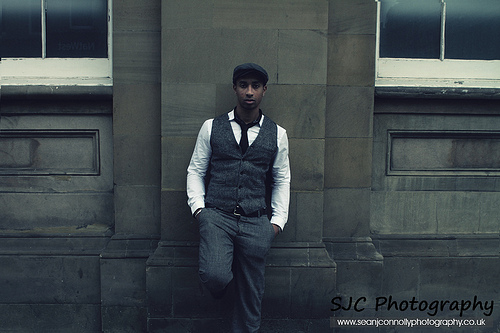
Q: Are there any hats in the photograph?
A: Yes, there is a hat.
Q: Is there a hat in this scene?
A: Yes, there is a hat.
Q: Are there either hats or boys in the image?
A: Yes, there is a hat.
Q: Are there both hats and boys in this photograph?
A: No, there is a hat but no boys.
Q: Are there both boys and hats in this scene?
A: No, there is a hat but no boys.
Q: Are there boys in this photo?
A: No, there are no boys.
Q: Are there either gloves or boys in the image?
A: No, there are no boys or gloves.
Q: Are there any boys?
A: No, there are no boys.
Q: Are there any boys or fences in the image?
A: No, there are no boys or fences.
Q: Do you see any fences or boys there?
A: No, there are no boys or fences.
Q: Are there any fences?
A: No, there are no fences.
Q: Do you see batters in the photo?
A: No, there are no batters.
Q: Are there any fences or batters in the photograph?
A: No, there are no batters or fences.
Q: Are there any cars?
A: No, there are no cars.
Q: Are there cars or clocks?
A: No, there are no cars or clocks.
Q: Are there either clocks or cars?
A: No, there are no cars or clocks.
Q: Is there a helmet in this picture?
A: No, there are no helmets.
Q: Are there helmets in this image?
A: No, there are no helmets.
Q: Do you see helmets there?
A: No, there are no helmets.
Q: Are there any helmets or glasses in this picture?
A: No, there are no helmets or glasses.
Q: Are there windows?
A: Yes, there is a window.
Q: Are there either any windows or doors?
A: Yes, there is a window.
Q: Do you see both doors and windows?
A: No, there is a window but no doors.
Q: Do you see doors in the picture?
A: No, there are no doors.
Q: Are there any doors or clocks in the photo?
A: No, there are no doors or clocks.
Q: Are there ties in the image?
A: Yes, there is a tie.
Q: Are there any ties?
A: Yes, there is a tie.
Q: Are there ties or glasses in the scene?
A: Yes, there is a tie.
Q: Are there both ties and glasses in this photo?
A: No, there is a tie but no glasses.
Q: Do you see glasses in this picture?
A: No, there are no glasses.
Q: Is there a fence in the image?
A: No, there are no fences.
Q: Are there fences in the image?
A: No, there are no fences.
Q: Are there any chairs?
A: No, there are no chairs.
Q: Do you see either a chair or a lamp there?
A: No, there are no chairs or lamps.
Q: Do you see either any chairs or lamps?
A: No, there are no chairs or lamps.